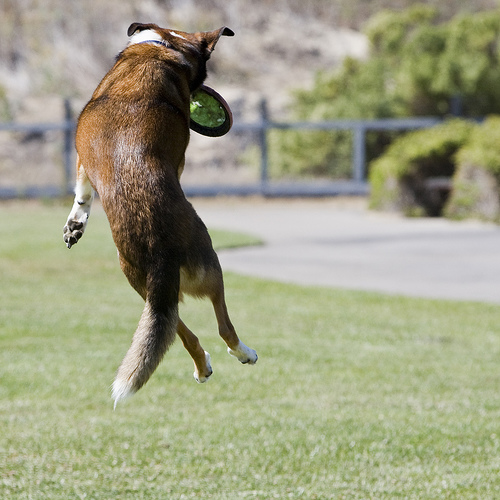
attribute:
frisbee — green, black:
[177, 76, 237, 140]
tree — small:
[282, 57, 407, 177]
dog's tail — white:
[108, 283, 188, 403]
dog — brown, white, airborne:
[72, 22, 257, 407]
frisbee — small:
[190, 80, 231, 137]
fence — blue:
[7, 116, 473, 198]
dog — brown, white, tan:
[57, 20, 259, 420]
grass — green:
[8, 207, 436, 492]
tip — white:
[106, 382, 141, 400]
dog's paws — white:
[58, 210, 92, 252]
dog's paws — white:
[226, 337, 264, 366]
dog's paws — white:
[194, 353, 210, 385]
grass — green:
[50, 300, 380, 479]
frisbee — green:
[190, 82, 235, 139]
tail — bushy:
[100, 279, 188, 404]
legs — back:
[139, 280, 261, 384]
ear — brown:
[194, 22, 239, 53]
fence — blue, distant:
[5, 101, 446, 197]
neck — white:
[125, 29, 208, 88]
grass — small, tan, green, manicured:
[5, 191, 498, 499]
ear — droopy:
[206, 22, 235, 49]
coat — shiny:
[75, 22, 222, 300]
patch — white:
[127, 30, 172, 50]